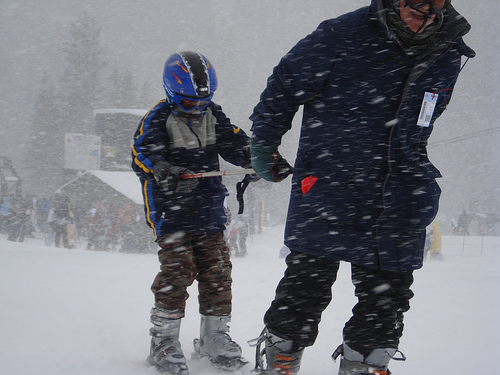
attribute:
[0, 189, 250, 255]
people — bunch of people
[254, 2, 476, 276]
jacket — black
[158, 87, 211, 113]
goggles — blue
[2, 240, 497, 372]
field — snowy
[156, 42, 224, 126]
helmet — blue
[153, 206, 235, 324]
pants — snow pants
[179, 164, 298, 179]
ski pole — White and red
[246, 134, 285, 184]
glove — green